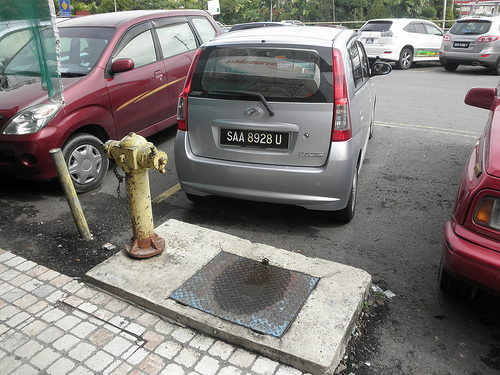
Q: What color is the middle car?
A: Silver.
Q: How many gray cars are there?
A: 2.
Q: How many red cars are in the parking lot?
A: Two.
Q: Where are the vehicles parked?
A: Parking lot.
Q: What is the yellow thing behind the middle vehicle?
A: Fire hydrant.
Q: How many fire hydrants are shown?
A: 1.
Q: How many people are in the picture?
A: None.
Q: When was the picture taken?
A: Daytime.